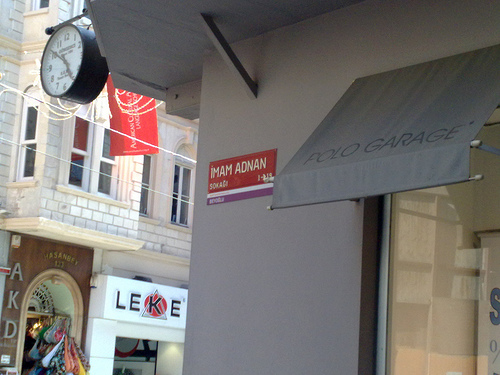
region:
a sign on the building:
[200, 158, 273, 198]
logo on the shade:
[303, 128, 445, 172]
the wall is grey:
[218, 242, 334, 362]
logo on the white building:
[109, 280, 186, 327]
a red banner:
[111, 115, 153, 145]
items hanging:
[40, 345, 90, 373]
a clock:
[31, 30, 93, 89]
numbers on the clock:
[50, 32, 79, 54]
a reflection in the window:
[394, 247, 481, 357]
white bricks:
[27, 193, 86, 215]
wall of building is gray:
[273, 273, 319, 328]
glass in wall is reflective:
[420, 277, 451, 317]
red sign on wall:
[205, 155, 271, 223]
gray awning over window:
[297, 125, 358, 181]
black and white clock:
[28, 52, 96, 82]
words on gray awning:
[305, 153, 435, 179]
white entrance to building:
[107, 295, 123, 340]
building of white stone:
[63, 225, 143, 226]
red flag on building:
[125, 118, 181, 166]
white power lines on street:
[31, 89, 84, 176]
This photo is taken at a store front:
[11, 15, 476, 354]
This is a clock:
[35, 6, 107, 102]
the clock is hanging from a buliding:
[22, 10, 117, 105]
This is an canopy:
[269, 69, 496, 211]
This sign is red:
[190, 143, 292, 207]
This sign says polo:
[292, 122, 494, 193]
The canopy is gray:
[325, 90, 493, 232]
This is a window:
[385, 244, 470, 327]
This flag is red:
[105, 96, 197, 186]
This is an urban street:
[4, 157, 220, 371]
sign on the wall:
[196, 148, 278, 206]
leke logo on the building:
[101, 285, 187, 323]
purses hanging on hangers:
[21, 318, 90, 373]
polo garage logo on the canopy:
[300, 120, 477, 174]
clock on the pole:
[35, 16, 104, 109]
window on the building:
[14, 104, 48, 189]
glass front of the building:
[408, 218, 455, 311]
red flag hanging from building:
[105, 95, 162, 155]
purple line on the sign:
[206, 192, 266, 207]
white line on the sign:
[207, 188, 233, 198]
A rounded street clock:
[37, 18, 109, 109]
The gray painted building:
[88, 0, 498, 374]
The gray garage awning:
[270, 48, 498, 210]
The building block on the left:
[0, 0, 198, 374]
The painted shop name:
[108, 279, 187, 328]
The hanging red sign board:
[107, 71, 160, 156]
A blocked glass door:
[362, 109, 499, 374]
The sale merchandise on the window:
[21, 309, 93, 372]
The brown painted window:
[0, 234, 95, 374]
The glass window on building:
[19, 95, 196, 227]